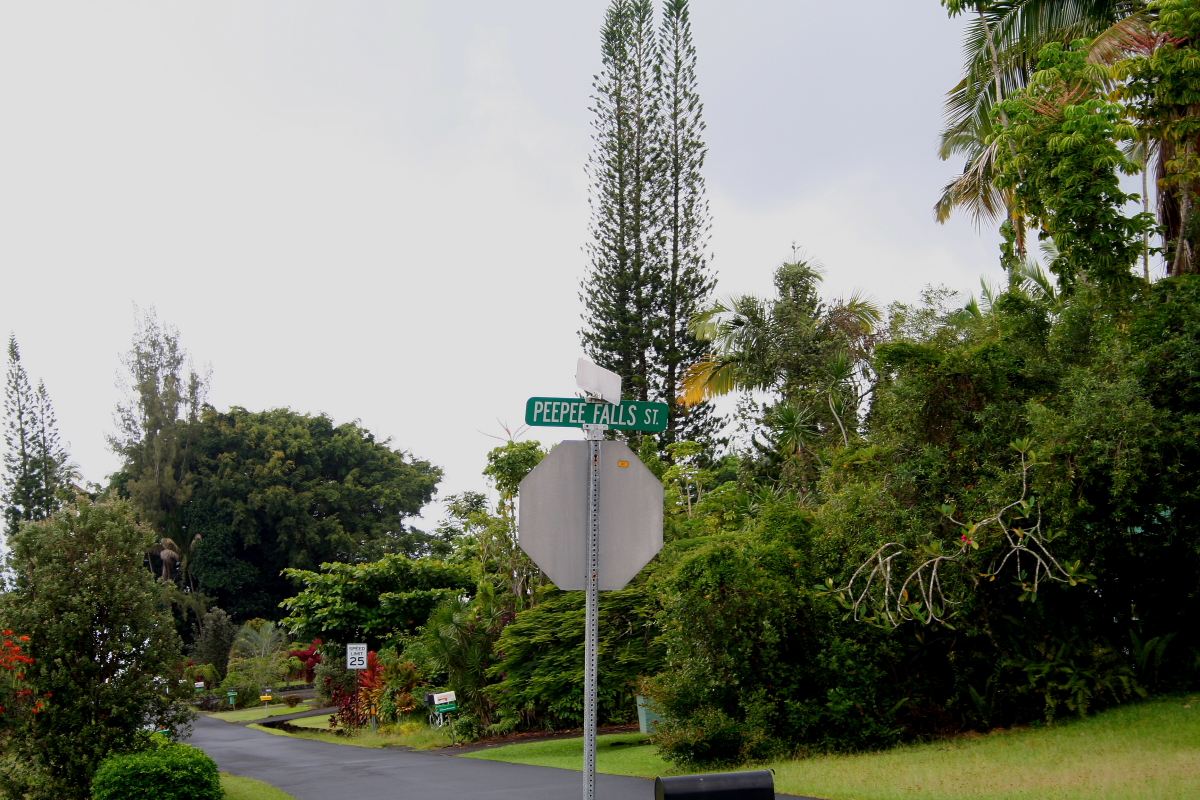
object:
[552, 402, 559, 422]
letter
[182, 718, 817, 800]
street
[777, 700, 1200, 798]
lawn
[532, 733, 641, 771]
lawn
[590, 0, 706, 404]
bush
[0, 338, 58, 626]
bush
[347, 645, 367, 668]
sign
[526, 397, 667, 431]
sign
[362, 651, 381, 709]
flowers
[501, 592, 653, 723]
bush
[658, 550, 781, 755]
bush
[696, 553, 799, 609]
leaves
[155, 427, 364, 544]
leaves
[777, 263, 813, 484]
tree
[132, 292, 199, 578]
tree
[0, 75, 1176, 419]
sky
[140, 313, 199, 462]
trees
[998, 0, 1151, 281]
woods